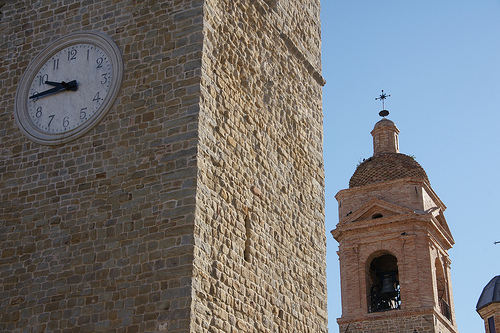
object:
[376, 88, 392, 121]
cross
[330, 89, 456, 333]
bell tower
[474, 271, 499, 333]
building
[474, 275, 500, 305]
roof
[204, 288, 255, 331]
brick wall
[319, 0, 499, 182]
sky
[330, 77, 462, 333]
tower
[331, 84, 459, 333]
building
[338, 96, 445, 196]
top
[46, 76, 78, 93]
hand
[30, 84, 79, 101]
hand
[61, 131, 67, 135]
stone ring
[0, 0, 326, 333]
brick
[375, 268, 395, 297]
bell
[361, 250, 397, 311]
opening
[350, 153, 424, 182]
roof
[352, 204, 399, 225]
triangle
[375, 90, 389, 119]
weather vane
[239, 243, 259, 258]
bricks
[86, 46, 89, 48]
dots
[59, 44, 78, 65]
numbers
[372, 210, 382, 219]
hole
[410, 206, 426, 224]
stones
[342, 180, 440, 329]
wall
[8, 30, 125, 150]
clock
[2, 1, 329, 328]
clock tower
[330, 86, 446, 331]
tower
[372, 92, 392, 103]
lightning rod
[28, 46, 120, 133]
english numerals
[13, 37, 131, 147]
clock face